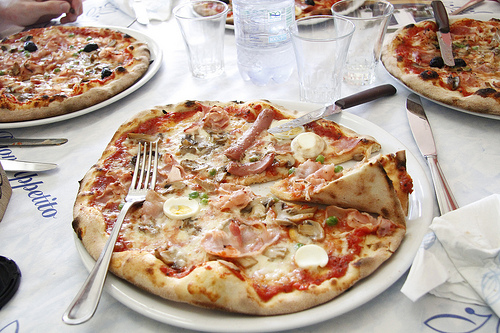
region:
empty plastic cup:
[176, 4, 239, 94]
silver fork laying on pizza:
[99, 131, 135, 329]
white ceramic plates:
[75, 116, 377, 328]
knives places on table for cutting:
[287, 84, 475, 186]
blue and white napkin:
[425, 191, 492, 303]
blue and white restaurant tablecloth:
[20, 196, 59, 269]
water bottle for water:
[239, 0, 306, 90]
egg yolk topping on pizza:
[162, 186, 212, 230]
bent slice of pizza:
[267, 113, 409, 219]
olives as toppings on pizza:
[80, 40, 122, 97]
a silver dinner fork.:
[60, 138, 157, 323]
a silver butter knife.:
[402, 90, 458, 215]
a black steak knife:
[265, 81, 396, 133]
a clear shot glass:
[170, 0, 227, 80]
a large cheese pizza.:
[71, 96, 412, 316]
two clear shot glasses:
[287, 1, 393, 106]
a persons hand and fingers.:
[0, 0, 81, 40]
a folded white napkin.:
[398, 191, 498, 317]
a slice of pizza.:
[268, 151, 408, 222]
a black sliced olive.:
[82, 41, 97, 53]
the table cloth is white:
[25, 225, 64, 288]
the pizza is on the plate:
[79, 85, 467, 327]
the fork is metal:
[72, 127, 184, 319]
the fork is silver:
[71, 117, 183, 328]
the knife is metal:
[391, 81, 487, 223]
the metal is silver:
[395, 75, 477, 232]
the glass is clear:
[170, 2, 247, 84]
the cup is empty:
[170, 0, 233, 85]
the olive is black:
[81, 52, 126, 92]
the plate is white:
[135, 282, 257, 331]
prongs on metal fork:
[134, 143, 150, 188]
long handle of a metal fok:
[74, 203, 119, 329]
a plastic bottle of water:
[231, 3, 283, 77]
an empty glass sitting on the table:
[176, 1, 221, 76]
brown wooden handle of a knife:
[341, 83, 394, 111]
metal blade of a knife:
[274, 104, 329, 134]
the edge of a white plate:
[174, 304, 215, 326]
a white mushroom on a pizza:
[161, 189, 199, 222]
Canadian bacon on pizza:
[220, 219, 262, 261]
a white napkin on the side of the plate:
[429, 217, 481, 278]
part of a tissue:
[441, 226, 486, 262]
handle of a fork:
[67, 287, 90, 313]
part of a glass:
[305, 55, 333, 85]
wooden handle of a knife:
[344, 89, 374, 103]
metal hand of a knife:
[434, 178, 447, 218]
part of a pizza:
[251, 191, 331, 274]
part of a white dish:
[384, 263, 401, 281]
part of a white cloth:
[31, 212, 59, 246]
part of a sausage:
[223, 139, 246, 168]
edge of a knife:
[400, 97, 417, 136]